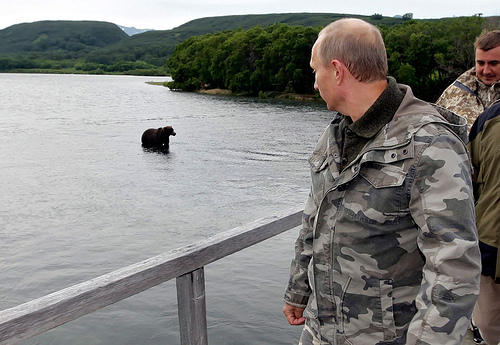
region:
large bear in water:
[139, 118, 181, 157]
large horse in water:
[143, 120, 187, 165]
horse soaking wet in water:
[130, 118, 183, 158]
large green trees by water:
[143, 21, 295, 92]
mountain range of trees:
[4, 10, 138, 64]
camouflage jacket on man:
[243, 99, 472, 307]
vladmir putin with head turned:
[298, 22, 397, 112]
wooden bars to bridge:
[32, 225, 254, 343]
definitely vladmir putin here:
[284, 25, 439, 343]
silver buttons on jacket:
[389, 148, 416, 161]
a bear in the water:
[139, 117, 179, 158]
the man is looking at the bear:
[277, 17, 482, 344]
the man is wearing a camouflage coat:
[291, 84, 484, 344]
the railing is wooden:
[0, 194, 306, 344]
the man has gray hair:
[304, 14, 394, 122]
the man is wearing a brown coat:
[431, 68, 498, 138]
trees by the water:
[162, 14, 497, 119]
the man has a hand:
[278, 297, 308, 327]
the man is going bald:
[310, 17, 392, 118]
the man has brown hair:
[467, 25, 497, 87]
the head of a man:
[281, 18, 420, 133]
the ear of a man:
[331, 51, 363, 116]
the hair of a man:
[307, 2, 409, 124]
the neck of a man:
[326, 36, 427, 141]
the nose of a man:
[294, 77, 343, 107]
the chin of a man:
[318, 66, 358, 128]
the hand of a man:
[265, 282, 335, 329]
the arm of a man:
[266, 188, 376, 311]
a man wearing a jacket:
[277, 79, 461, 303]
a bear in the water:
[138, 115, 210, 172]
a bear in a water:
[127, 108, 179, 157]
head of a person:
[297, 0, 406, 125]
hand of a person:
[275, 293, 316, 327]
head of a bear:
[163, 125, 178, 137]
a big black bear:
[126, 123, 195, 158]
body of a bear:
[135, 129, 161, 144]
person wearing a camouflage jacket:
[269, 20, 474, 344]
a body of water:
[27, 85, 124, 147]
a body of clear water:
[19, 94, 106, 139]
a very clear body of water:
[22, 90, 107, 145]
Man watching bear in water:
[281, 17, 481, 344]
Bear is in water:
[140, 117, 180, 162]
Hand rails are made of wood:
[1, 202, 303, 342]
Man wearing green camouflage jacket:
[287, 85, 479, 344]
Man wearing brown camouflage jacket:
[437, 73, 499, 129]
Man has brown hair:
[468, 25, 498, 50]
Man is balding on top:
[306, 14, 391, 88]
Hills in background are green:
[0, 7, 498, 99]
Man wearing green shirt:
[309, 73, 401, 160]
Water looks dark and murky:
[3, 74, 330, 344]